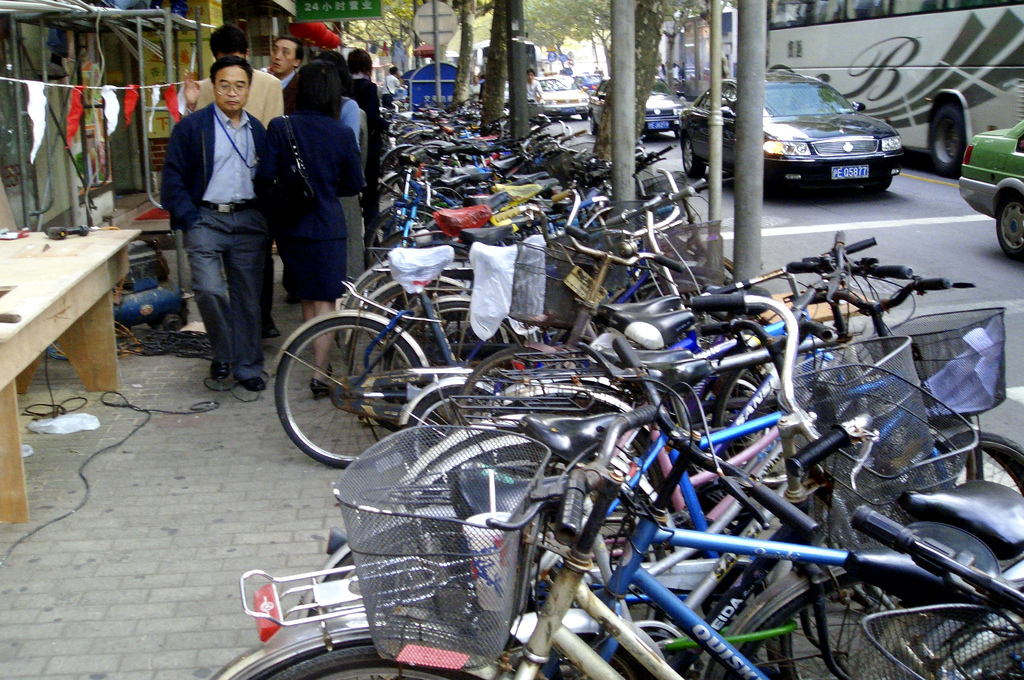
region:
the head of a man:
[190, 63, 260, 118]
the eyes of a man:
[212, 70, 250, 94]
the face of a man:
[214, 66, 250, 117]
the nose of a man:
[224, 88, 243, 99]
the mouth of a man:
[224, 94, 241, 111]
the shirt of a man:
[148, 100, 279, 217]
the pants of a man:
[168, 205, 285, 382]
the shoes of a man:
[195, 341, 259, 403]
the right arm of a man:
[143, 119, 208, 233]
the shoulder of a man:
[247, 116, 267, 148]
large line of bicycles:
[333, 81, 1004, 660]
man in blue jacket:
[136, 50, 272, 405]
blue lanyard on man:
[206, 98, 258, 187]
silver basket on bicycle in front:
[320, 418, 562, 656]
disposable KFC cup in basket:
[449, 462, 548, 627]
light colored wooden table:
[0, 209, 172, 513]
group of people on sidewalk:
[141, 19, 411, 413]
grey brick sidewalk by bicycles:
[23, 309, 396, 660]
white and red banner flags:
[5, 75, 294, 149]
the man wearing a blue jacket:
[160, 57, 282, 391]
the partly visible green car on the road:
[957, 113, 1022, 260]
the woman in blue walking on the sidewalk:
[261, 61, 367, 397]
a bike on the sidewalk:
[541, 367, 698, 580]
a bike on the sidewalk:
[541, 373, 707, 501]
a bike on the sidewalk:
[503, 370, 1020, 489]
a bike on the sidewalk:
[450, 317, 739, 445]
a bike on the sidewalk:
[356, 259, 569, 399]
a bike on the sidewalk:
[354, 186, 552, 323]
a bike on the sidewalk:
[228, 116, 511, 259]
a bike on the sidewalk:
[453, 113, 561, 341]